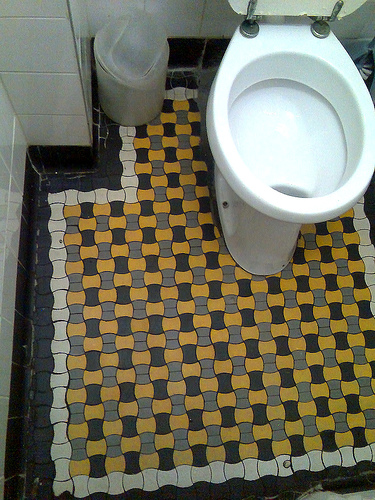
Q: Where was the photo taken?
A: It was taken at the bathroom.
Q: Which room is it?
A: It is a bathroom.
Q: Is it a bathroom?
A: Yes, it is a bathroom.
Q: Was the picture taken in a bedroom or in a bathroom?
A: It was taken at a bathroom.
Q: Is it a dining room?
A: No, it is a bathroom.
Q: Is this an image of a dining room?
A: No, the picture is showing a bathroom.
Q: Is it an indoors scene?
A: Yes, it is indoors.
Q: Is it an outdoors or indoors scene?
A: It is indoors.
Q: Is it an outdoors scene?
A: No, it is indoors.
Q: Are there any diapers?
A: No, there are no diapers.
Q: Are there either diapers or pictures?
A: No, there are no diapers or pictures.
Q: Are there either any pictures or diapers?
A: No, there are no diapers or pictures.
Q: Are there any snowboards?
A: No, there are no snowboards.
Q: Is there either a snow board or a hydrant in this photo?
A: No, there are no snowboards or fire hydrants.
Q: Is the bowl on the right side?
A: Yes, the bowl is on the right of the image.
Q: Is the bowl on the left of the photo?
A: No, the bowl is on the right of the image.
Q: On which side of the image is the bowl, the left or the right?
A: The bowl is on the right of the image.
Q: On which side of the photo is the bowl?
A: The bowl is on the right of the image.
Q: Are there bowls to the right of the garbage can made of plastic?
A: Yes, there is a bowl to the right of the trash bin.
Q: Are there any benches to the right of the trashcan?
A: No, there is a bowl to the right of the trashcan.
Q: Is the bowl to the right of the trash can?
A: Yes, the bowl is to the right of the trash can.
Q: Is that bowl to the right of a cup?
A: No, the bowl is to the right of the trash can.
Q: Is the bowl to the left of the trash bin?
A: No, the bowl is to the right of the trash bin.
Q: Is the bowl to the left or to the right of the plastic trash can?
A: The bowl is to the right of the garbage can.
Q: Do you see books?
A: No, there are no books.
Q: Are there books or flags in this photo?
A: No, there are no books or flags.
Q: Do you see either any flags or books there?
A: No, there are no books or flags.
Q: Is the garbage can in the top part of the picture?
A: Yes, the garbage can is in the top of the image.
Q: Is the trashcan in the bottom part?
A: No, the trashcan is in the top of the image.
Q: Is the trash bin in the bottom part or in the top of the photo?
A: The trash bin is in the top of the image.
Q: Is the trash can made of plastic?
A: Yes, the trash can is made of plastic.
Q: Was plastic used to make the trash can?
A: Yes, the trash can is made of plastic.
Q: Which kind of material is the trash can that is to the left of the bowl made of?
A: The trash bin is made of plastic.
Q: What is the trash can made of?
A: The trash bin is made of plastic.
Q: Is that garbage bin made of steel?
A: No, the garbage bin is made of plastic.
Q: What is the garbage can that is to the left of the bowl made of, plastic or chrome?
A: The trashcan is made of plastic.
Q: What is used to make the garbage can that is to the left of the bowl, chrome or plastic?
A: The trashcan is made of plastic.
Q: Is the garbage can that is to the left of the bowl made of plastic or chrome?
A: The trashcan is made of plastic.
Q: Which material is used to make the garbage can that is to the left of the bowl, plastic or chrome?
A: The trashcan is made of plastic.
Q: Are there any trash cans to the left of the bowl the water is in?
A: Yes, there is a trash can to the left of the bowl.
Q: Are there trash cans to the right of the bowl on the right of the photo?
A: No, the trash can is to the left of the bowl.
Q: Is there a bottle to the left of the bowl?
A: No, there is a trash can to the left of the bowl.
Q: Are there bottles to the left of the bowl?
A: No, there is a trash can to the left of the bowl.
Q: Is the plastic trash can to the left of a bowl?
A: Yes, the trash can is to the left of a bowl.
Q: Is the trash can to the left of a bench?
A: No, the trash can is to the left of a bowl.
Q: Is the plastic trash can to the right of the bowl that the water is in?
A: No, the trash bin is to the left of the bowl.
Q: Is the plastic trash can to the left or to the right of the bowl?
A: The trash bin is to the left of the bowl.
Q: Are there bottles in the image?
A: No, there are no bottles.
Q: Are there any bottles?
A: No, there are no bottles.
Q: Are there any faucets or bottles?
A: No, there are no bottles or faucets.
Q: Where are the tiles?
A: The tiles are on the floor.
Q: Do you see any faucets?
A: No, there are no faucets.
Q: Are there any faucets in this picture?
A: No, there are no faucets.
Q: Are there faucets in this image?
A: No, there are no faucets.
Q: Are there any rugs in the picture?
A: No, there are no rugs.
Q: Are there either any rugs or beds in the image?
A: No, there are no rugs or beds.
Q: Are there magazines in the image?
A: No, there are no magazines.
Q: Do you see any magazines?
A: No, there are no magazines.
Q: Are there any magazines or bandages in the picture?
A: No, there are no magazines or bandages.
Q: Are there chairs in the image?
A: No, there are no chairs.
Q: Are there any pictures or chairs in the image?
A: No, there are no chairs or pictures.